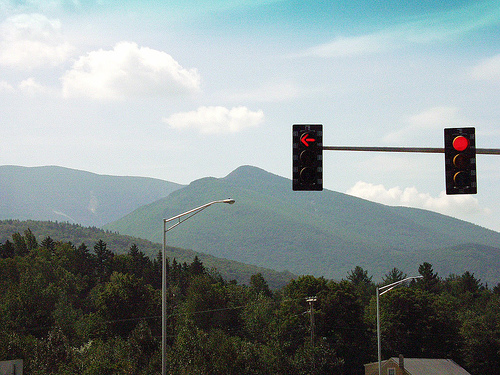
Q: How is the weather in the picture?
A: It is cloudy.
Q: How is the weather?
A: It is cloudy.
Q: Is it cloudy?
A: Yes, it is cloudy.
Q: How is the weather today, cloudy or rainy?
A: It is cloudy.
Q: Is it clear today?
A: No, it is cloudy.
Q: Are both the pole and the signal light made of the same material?
A: Yes, both the pole and the signal light are made of metal.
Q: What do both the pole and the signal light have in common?
A: The material, both the pole and the signal light are metallic.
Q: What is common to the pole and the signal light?
A: The material, both the pole and the signal light are metallic.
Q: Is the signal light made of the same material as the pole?
A: Yes, both the signal light and the pole are made of metal.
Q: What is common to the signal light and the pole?
A: The material, both the signal light and the pole are metallic.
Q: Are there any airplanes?
A: No, there are no airplanes.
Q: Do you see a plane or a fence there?
A: No, there are no airplanes or fences.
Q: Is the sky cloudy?
A: Yes, the sky is cloudy.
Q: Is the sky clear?
A: No, the sky is cloudy.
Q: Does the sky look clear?
A: No, the sky is cloudy.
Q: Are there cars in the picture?
A: No, there are no cars.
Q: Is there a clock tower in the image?
A: No, there are no clock towers.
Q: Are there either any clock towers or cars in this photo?
A: No, there are no clock towers or cars.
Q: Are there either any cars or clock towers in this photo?
A: No, there are no clock towers or cars.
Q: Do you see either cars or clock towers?
A: No, there are no clock towers or cars.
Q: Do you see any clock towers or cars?
A: No, there are no clock towers or cars.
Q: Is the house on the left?
A: No, the house is on the right of the image.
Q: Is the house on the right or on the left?
A: The house is on the right of the image.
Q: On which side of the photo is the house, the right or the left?
A: The house is on the right of the image.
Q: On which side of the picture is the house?
A: The house is on the right of the image.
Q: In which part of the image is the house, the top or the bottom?
A: The house is in the bottom of the image.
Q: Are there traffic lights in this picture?
A: Yes, there is a traffic light.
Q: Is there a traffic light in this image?
A: Yes, there is a traffic light.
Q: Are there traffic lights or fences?
A: Yes, there is a traffic light.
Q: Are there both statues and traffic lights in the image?
A: No, there is a traffic light but no statues.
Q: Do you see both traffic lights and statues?
A: No, there is a traffic light but no statues.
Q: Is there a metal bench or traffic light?
A: Yes, there is a metal traffic light.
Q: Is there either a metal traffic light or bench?
A: Yes, there is a metal traffic light.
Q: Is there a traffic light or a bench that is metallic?
A: Yes, the traffic light is metallic.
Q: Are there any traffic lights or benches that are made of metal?
A: Yes, the traffic light is made of metal.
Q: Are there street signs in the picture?
A: No, there are no street signs.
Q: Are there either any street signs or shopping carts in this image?
A: No, there are no street signs or shopping carts.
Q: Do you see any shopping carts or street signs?
A: No, there are no street signs or shopping carts.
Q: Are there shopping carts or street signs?
A: No, there are no street signs or shopping carts.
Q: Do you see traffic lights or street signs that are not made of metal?
A: No, there is a traffic light but it is made of metal.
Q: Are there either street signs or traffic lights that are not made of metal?
A: No, there is a traffic light but it is made of metal.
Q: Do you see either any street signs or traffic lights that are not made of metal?
A: No, there is a traffic light but it is made of metal.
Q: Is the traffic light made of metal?
A: Yes, the traffic light is made of metal.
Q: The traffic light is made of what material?
A: The traffic light is made of metal.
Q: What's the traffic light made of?
A: The traffic light is made of metal.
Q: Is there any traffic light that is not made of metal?
A: No, there is a traffic light but it is made of metal.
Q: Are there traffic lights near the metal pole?
A: Yes, there is a traffic light near the pole.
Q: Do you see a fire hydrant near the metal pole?
A: No, there is a traffic light near the pole.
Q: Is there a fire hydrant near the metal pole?
A: No, there is a traffic light near the pole.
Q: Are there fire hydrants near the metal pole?
A: No, there is a traffic light near the pole.